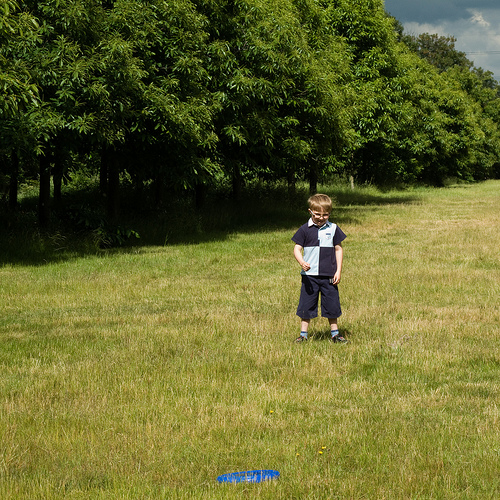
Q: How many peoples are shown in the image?
A: One.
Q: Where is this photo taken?
A: A field.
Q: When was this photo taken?
A: Day time.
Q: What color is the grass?
A: Yellow.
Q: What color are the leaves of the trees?
A: Green.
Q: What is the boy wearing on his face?
A: Glasses.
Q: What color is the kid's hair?
A: Blonde.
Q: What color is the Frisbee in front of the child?
A: Blue.